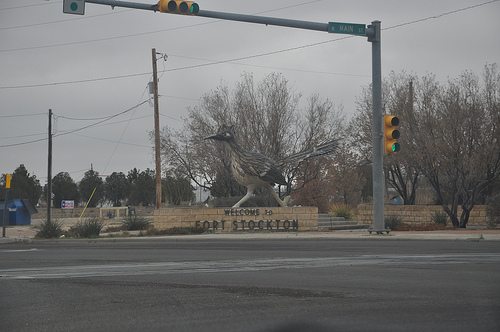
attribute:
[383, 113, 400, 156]
street light — yellow, green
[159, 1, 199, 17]
street light — yellow, green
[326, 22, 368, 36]
sign — green, long, white, rectangle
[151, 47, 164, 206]
light pole — tall, brown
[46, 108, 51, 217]
light pole — tall, brown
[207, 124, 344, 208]
statue — bird, brown, giant, symbol, roadrunner, running bird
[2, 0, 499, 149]
electrical lines — long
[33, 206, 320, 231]
wall — long, brick, light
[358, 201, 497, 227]
wall — brick, light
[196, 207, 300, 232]
letters — black, capitals, welcoming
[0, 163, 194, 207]
trees — green, tall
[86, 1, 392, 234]
pole — gray, tall, metal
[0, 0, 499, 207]
sky — cloudy, gray, bleak, depressing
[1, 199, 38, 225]
dumpster — blue, steel, small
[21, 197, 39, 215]
lid — black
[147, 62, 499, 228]
trees — bare, leafless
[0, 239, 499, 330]
street — gray, asphalt